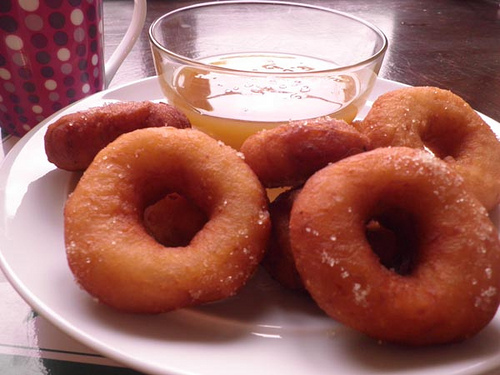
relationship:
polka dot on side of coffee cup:
[28, 31, 49, 50] [0, 0, 148, 137]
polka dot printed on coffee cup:
[28, 31, 49, 50] [0, 0, 148, 137]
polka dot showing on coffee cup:
[57, 48, 71, 62] [0, 0, 148, 137]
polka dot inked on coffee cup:
[28, 31, 49, 50] [0, 0, 148, 137]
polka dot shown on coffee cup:
[28, 31, 49, 50] [0, 0, 148, 137]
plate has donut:
[0, 74, 500, 375] [63, 125, 273, 316]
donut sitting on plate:
[288, 145, 500, 345] [0, 74, 500, 375]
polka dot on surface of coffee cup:
[28, 31, 49, 50] [0, 0, 148, 137]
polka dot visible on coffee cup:
[28, 31, 49, 50] [0, 0, 148, 137]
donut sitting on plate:
[63, 125, 273, 316] [0, 74, 500, 375]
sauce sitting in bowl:
[174, 51, 361, 153] [147, 0, 389, 153]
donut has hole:
[63, 125, 273, 316] [142, 188, 211, 247]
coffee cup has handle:
[0, 0, 148, 137] [104, 0, 148, 90]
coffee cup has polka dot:
[0, 0, 148, 137] [11, 52, 29, 68]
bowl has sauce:
[147, 0, 389, 153] [174, 51, 361, 153]